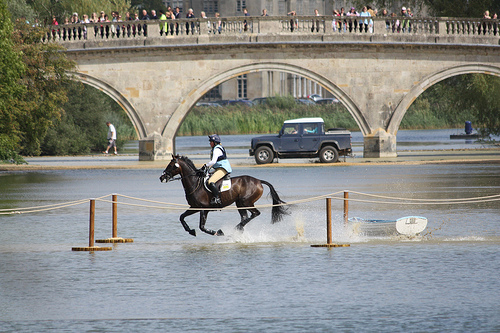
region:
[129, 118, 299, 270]
a brown horse galloping through water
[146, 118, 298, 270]
a man riding through shallow water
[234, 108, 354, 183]
a blue truck under a bridge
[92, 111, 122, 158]
a walking man in a white shirt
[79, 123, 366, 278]
a horserider traversing through a rope course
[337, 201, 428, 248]
a tiny white boat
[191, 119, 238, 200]
a person with blue shorts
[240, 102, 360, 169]
a truck with a white roof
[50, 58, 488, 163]
a stone arched bridge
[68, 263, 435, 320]
shallow blue water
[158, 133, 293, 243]
a black horse galloping through water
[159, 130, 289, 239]
a man riding a rhose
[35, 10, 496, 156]
a long arched bridge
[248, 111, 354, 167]
a parked blue truck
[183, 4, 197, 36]
spectator watching from bridge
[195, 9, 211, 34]
spectator watching from bridge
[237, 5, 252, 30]
spectator watching from bridge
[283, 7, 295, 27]
spectator watching from bridge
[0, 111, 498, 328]
a shallow body of water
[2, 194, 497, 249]
guide ropes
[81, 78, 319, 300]
a horse galloping through water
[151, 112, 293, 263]
a man on a horse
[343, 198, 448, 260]
a white boat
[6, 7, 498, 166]
people on a bridge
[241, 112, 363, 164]
a truck under the bridge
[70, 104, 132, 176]
a man walking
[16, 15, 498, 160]
a bridge made of stone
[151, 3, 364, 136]
parked cars in front of a building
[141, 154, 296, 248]
a black horse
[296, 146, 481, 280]
a boat on water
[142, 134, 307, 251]
A horse crossing water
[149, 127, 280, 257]
a person riding a horse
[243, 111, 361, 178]
a vehicle crossing the water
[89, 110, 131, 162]
A man in white shirt and gray shorts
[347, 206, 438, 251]
A small white boat with blue trim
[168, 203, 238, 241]
Front feet of horse in the air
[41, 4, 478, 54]
People gathered on top of bridge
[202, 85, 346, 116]
Cars parked in front of building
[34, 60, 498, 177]
Three arches under bridge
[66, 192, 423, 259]
Poles holding guiding ropes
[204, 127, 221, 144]
a dark helmet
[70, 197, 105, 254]
a brown pole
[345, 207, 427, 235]
a blue and white boat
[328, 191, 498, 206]
a brown rope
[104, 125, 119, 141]
a man's short sleeve white shirt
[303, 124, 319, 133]
the window of an suv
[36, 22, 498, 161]
a tall gray bridge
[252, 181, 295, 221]
the tail of a horse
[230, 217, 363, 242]
white splashing water